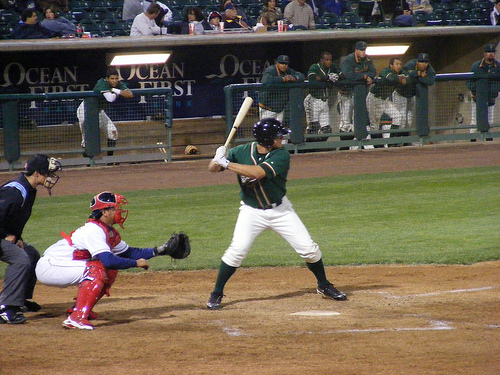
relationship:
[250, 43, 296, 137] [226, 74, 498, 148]
player standing at rail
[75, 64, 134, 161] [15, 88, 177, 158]
baseball player standing at rail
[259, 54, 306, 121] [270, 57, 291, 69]
player wearing a baseball hat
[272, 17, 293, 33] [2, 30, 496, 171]
soda cup on top of dugout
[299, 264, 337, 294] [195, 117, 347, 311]
sock of player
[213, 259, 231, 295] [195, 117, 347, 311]
sock of player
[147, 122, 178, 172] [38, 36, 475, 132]
bats at dugout